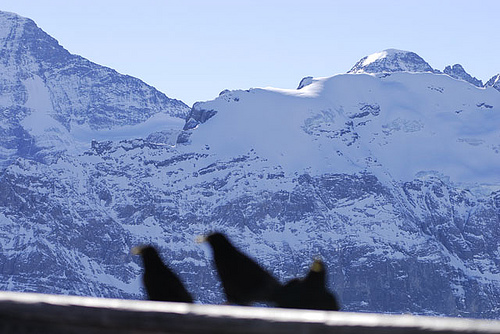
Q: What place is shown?
A: It is a field.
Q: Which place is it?
A: It is a field.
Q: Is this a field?
A: Yes, it is a field.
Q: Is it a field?
A: Yes, it is a field.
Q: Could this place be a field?
A: Yes, it is a field.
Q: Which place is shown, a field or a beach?
A: It is a field.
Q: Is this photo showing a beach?
A: No, the picture is showing a field.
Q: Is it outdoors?
A: Yes, it is outdoors.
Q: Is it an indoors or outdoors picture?
A: It is outdoors.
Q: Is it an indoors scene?
A: No, it is outdoors.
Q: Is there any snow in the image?
A: Yes, there is snow.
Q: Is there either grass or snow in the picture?
A: Yes, there is snow.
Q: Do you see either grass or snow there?
A: Yes, there is snow.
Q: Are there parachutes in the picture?
A: No, there are no parachutes.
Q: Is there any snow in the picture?
A: Yes, there is snow.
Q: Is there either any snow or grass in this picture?
A: Yes, there is snow.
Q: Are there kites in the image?
A: No, there are no kites.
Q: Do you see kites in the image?
A: No, there are no kites.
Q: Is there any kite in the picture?
A: No, there are no kites.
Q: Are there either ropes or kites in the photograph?
A: No, there are no kites or ropes.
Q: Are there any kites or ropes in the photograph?
A: No, there are no kites or ropes.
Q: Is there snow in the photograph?
A: Yes, there is snow.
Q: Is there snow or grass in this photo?
A: Yes, there is snow.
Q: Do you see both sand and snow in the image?
A: No, there is snow but no sand.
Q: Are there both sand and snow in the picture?
A: No, there is snow but no sand.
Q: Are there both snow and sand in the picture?
A: No, there is snow but no sand.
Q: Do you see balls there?
A: No, there are no balls.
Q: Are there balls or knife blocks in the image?
A: No, there are no balls or knife blocks.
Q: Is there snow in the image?
A: Yes, there is snow.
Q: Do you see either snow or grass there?
A: Yes, there is snow.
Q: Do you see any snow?
A: Yes, there is snow.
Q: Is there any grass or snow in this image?
A: Yes, there is snow.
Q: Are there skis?
A: No, there are no skis.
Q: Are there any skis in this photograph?
A: No, there are no skis.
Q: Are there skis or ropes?
A: No, there are no skis or ropes.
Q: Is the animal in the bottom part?
A: Yes, the animal is in the bottom of the image.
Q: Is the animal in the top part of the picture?
A: No, the animal is in the bottom of the image.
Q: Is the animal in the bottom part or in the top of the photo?
A: The animal is in the bottom of the image.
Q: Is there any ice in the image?
A: Yes, there is ice.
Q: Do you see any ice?
A: Yes, there is ice.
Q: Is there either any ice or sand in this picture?
A: Yes, there is ice.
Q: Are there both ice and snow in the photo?
A: Yes, there are both ice and snow.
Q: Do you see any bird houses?
A: No, there are no bird houses.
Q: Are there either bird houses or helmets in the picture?
A: No, there are no bird houses or helmets.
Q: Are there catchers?
A: No, there are no catchers.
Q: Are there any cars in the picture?
A: No, there are no cars.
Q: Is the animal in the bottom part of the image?
A: Yes, the animal is in the bottom of the image.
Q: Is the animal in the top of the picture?
A: No, the animal is in the bottom of the image.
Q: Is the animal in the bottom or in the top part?
A: The animal is in the bottom of the image.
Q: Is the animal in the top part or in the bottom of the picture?
A: The animal is in the bottom of the image.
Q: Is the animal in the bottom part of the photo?
A: Yes, the animal is in the bottom of the image.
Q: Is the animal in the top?
A: No, the animal is in the bottom of the image.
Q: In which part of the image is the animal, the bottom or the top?
A: The animal is in the bottom of the image.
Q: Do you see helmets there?
A: No, there are no helmets.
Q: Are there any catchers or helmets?
A: No, there are no helmets or catchers.